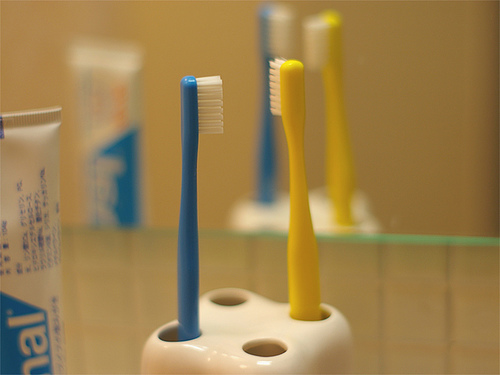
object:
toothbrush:
[177, 74, 224, 341]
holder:
[140, 286, 353, 374]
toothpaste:
[0, 106, 68, 374]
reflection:
[66, 0, 381, 234]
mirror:
[0, 0, 500, 238]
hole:
[241, 337, 288, 357]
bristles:
[194, 75, 223, 136]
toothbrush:
[268, 55, 321, 320]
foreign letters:
[0, 166, 65, 374]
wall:
[61, 232, 499, 374]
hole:
[208, 288, 249, 307]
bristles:
[268, 56, 290, 117]